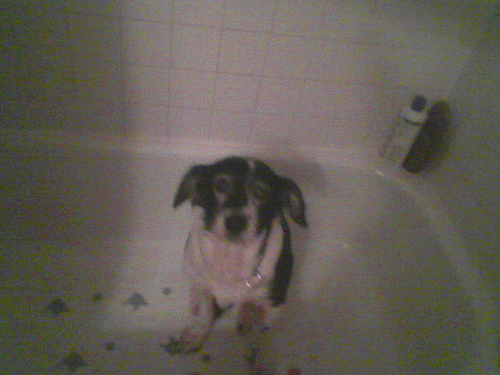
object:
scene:
[0, 0, 499, 374]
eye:
[214, 177, 230, 192]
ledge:
[380, 154, 499, 373]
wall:
[0, 0, 499, 152]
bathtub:
[0, 140, 499, 374]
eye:
[250, 183, 266, 199]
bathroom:
[0, 0, 498, 373]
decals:
[42, 295, 71, 316]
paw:
[162, 323, 207, 355]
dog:
[170, 154, 307, 363]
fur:
[209, 248, 247, 269]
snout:
[220, 215, 252, 243]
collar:
[245, 220, 273, 275]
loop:
[243, 269, 263, 287]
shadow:
[279, 141, 337, 188]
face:
[201, 160, 276, 236]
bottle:
[379, 95, 427, 164]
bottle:
[403, 100, 449, 172]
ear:
[277, 175, 309, 228]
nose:
[224, 211, 250, 231]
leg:
[180, 283, 213, 342]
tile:
[170, 21, 221, 72]